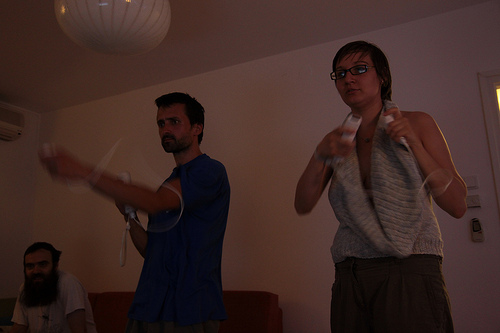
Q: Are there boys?
A: No, there are no boys.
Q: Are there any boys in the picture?
A: No, there are no boys.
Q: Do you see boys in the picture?
A: No, there are no boys.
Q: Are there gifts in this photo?
A: No, there are no gifts.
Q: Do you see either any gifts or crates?
A: No, there are no gifts or crates.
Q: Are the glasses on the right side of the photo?
A: Yes, the glasses are on the right of the image.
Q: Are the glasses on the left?
A: No, the glasses are on the right of the image.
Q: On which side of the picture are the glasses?
A: The glasses are on the right of the image.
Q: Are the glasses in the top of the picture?
A: Yes, the glasses are in the top of the image.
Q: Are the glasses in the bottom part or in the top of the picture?
A: The glasses are in the top of the image.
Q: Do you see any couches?
A: Yes, there is a couch.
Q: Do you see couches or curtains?
A: Yes, there is a couch.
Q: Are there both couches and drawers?
A: No, there is a couch but no drawers.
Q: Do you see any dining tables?
A: No, there are no dining tables.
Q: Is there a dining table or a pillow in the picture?
A: No, there are no dining tables or pillows.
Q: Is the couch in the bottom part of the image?
A: Yes, the couch is in the bottom of the image.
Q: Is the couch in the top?
A: No, the couch is in the bottom of the image.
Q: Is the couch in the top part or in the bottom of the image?
A: The couch is in the bottom of the image.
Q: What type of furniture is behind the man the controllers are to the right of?
A: The piece of furniture is a couch.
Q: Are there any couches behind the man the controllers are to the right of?
A: Yes, there is a couch behind the man.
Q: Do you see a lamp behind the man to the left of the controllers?
A: No, there is a couch behind the man.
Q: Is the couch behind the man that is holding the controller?
A: Yes, the couch is behind the man.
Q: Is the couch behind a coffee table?
A: No, the couch is behind the man.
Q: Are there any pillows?
A: No, there are no pillows.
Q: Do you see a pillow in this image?
A: No, there are no pillows.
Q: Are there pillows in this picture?
A: No, there are no pillows.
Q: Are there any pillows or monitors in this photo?
A: No, there are no pillows or monitors.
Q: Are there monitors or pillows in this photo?
A: No, there are no pillows or monitors.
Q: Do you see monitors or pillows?
A: No, there are no pillows or monitors.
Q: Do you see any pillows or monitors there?
A: No, there are no pillows or monitors.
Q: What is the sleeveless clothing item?
A: The clothing item is a sweater.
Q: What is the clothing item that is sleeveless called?
A: The clothing item is a sweater.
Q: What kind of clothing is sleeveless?
A: The clothing is a sweater.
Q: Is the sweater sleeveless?
A: Yes, the sweater is sleeveless.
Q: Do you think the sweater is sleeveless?
A: Yes, the sweater is sleeveless.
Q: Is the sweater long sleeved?
A: No, the sweater is sleeveless.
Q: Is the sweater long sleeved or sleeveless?
A: The sweater is sleeveless.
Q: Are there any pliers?
A: No, there are no pliers.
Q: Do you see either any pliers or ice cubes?
A: No, there are no pliers or ice cubes.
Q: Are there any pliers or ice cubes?
A: No, there are no pliers or ice cubes.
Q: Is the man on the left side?
A: Yes, the man is on the left of the image.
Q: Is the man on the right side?
A: No, the man is on the left of the image.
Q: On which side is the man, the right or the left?
A: The man is on the left of the image.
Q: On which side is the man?
A: The man is on the left of the image.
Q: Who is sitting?
A: The man is sitting.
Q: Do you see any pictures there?
A: No, there are no pictures.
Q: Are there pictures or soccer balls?
A: No, there are no pictures or soccer balls.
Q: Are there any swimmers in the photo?
A: No, there are no swimmers.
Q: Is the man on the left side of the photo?
A: Yes, the man is on the left of the image.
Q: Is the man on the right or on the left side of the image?
A: The man is on the left of the image.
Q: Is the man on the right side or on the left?
A: The man is on the left of the image.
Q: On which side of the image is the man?
A: The man is on the left of the image.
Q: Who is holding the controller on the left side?
A: The man is holding the controller.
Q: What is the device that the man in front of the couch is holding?
A: The device is a controller.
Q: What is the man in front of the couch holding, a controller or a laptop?
A: The man is holding a controller.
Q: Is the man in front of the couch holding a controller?
A: Yes, the man is holding a controller.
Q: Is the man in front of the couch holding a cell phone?
A: No, the man is holding a controller.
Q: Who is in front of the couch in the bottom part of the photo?
A: The man is in front of the couch.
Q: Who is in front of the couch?
A: The man is in front of the couch.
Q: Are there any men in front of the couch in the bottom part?
A: Yes, there is a man in front of the couch.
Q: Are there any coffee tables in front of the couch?
A: No, there is a man in front of the couch.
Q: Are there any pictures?
A: No, there are no pictures.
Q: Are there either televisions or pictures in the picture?
A: No, there are no pictures or televisions.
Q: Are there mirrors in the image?
A: No, there are no mirrors.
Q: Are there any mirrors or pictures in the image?
A: No, there are no mirrors or pictures.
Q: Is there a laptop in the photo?
A: No, there are no laptops.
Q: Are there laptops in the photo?
A: No, there are no laptops.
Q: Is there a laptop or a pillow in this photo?
A: No, there are no laptops or pillows.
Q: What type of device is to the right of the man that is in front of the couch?
A: The devices are controllers.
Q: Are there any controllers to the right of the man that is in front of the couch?
A: Yes, there are controllers to the right of the man.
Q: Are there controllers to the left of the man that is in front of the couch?
A: No, the controllers are to the right of the man.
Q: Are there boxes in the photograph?
A: No, there are no boxes.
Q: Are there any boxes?
A: No, there are no boxes.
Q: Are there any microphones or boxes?
A: No, there are no boxes or microphones.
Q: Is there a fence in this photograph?
A: No, there are no fences.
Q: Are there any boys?
A: No, there are no boys.